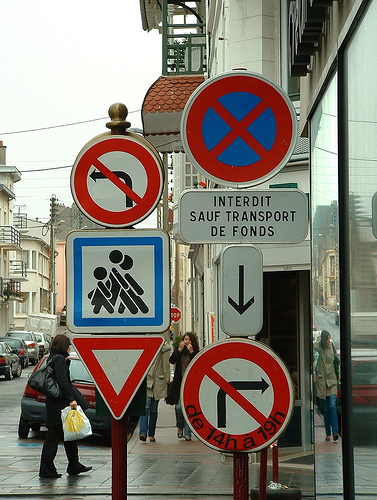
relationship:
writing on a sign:
[185, 403, 287, 450] [179, 337, 294, 456]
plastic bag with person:
[59, 407, 97, 442] [46, 331, 76, 377]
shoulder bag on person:
[28, 353, 64, 400] [28, 333, 92, 478]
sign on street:
[177, 67, 299, 187] [0, 358, 311, 497]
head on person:
[47, 331, 75, 358] [25, 329, 95, 484]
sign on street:
[177, 67, 299, 187] [0, 343, 45, 449]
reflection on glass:
[310, 324, 347, 442] [294, 57, 374, 495]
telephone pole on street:
[43, 190, 66, 322] [1, 330, 197, 488]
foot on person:
[148, 432, 158, 442] [136, 325, 176, 453]